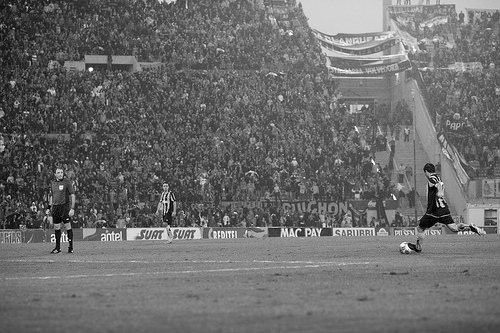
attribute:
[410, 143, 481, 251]
soccer player — running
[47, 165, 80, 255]
referee — standing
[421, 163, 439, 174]
hair — dark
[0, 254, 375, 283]
lines — white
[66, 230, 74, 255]
sock — dark, black, high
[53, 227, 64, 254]
sock — dark, black, high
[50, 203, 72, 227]
shorts — dark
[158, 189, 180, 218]
shirt — striped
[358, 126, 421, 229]
stairwell — large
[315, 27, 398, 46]
banner — hanging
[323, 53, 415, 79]
banner — hanging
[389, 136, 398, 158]
people — walking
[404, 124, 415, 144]
people — walking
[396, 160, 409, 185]
people — walking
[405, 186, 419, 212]
people — walking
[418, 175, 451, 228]
uniform — black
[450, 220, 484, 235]
leg — back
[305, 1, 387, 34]
sky — grey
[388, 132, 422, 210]
rail — metal